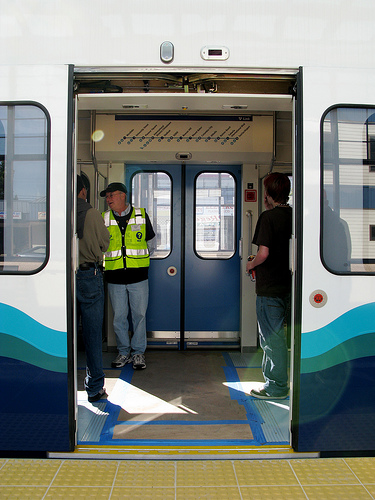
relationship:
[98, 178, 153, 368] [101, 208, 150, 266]
man in vest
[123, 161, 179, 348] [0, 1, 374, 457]
door of train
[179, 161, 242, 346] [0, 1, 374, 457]
door of train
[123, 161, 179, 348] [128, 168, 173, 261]
door has window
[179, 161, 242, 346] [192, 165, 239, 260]
door has window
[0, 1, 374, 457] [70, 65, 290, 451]
train has doorway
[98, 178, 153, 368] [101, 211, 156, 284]
man in shirt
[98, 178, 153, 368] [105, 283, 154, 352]
man in jeans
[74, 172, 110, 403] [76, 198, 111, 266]
man wearing shirt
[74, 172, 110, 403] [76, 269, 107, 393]
man wearing jeans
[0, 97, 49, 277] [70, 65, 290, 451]
window left of doorway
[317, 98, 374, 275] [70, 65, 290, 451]
window right of doorway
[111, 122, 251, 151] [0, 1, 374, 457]
guide for train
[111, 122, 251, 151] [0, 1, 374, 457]
guide of train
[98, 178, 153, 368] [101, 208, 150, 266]
man wearing vest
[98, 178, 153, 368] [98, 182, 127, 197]
man wearing cap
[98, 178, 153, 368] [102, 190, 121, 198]
man wearing glasses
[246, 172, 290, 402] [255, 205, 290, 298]
man wearing shirt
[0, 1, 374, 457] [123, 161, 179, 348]
train has door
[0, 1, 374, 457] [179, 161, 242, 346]
train has door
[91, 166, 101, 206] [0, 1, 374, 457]
grab bar on train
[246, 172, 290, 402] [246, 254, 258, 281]
man holding drink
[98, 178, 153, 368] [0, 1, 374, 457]
man on train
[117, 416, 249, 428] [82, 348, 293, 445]
line on floor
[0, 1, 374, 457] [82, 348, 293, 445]
train has floor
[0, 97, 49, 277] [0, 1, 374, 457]
window side of train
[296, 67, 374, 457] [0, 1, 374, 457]
door side of train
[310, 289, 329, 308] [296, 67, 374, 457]
handle on door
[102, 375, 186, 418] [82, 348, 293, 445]
light shining on floor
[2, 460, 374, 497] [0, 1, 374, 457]
platform for train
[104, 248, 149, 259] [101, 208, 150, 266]
line on vest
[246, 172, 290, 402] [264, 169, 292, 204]
man has hair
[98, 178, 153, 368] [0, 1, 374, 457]
man inside train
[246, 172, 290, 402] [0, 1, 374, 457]
man inside train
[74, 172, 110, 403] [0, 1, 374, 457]
man inside train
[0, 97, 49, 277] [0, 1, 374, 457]
window of train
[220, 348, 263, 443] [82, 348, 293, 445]
line on floor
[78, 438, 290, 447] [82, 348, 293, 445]
line on floor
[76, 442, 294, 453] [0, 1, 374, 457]
doorstep of train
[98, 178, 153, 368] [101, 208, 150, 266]
man wears vest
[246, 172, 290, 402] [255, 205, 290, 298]
man wears shirt